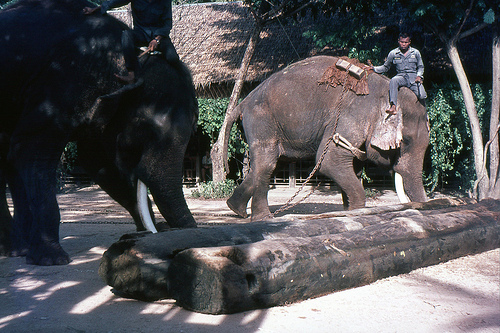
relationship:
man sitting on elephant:
[369, 25, 437, 117] [229, 41, 454, 232]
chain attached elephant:
[264, 70, 356, 218] [221, 55, 433, 222]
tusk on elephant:
[119, 184, 197, 248] [14, 27, 289, 217]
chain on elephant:
[58, 63, 352, 226] [221, 55, 433, 222]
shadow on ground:
[1, 205, 269, 330] [1, 190, 498, 331]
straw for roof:
[207, 34, 220, 61] [188, 3, 263, 79]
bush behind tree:
[425, 80, 481, 184] [445, 67, 496, 168]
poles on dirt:
[83, 202, 460, 292] [7, 248, 497, 330]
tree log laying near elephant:
[166, 199, 498, 316] [221, 55, 433, 222]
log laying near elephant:
[96, 195, 493, 315] [2, 0, 196, 267]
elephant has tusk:
[213, 47, 455, 219] [385, 155, 430, 212]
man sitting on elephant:
[369, 25, 437, 117] [221, 55, 433, 222]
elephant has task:
[127, 171, 162, 247] [132, 182, 161, 231]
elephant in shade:
[2, 0, 196, 267] [59, 208, 264, 283]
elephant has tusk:
[2, 0, 196, 267] [119, 184, 197, 248]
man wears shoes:
[369, 25, 437, 117] [379, 104, 400, 120]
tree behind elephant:
[204, 20, 254, 192] [216, 55, 436, 208]